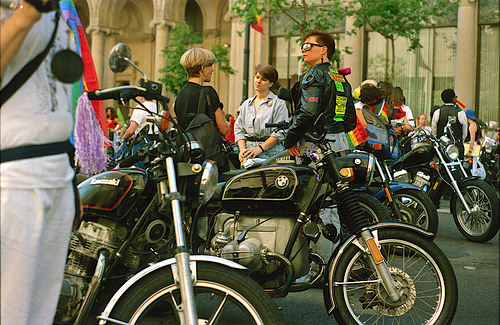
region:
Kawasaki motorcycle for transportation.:
[74, 48, 277, 323]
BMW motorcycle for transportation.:
[228, 127, 450, 323]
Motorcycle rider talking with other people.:
[282, 22, 365, 294]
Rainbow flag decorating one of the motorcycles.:
[328, 107, 398, 169]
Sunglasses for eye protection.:
[297, 35, 332, 55]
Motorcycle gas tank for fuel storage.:
[225, 159, 322, 226]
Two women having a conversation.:
[169, 42, 294, 154]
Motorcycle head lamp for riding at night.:
[180, 150, 236, 214]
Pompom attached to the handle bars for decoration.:
[64, 85, 111, 193]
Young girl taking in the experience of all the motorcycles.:
[411, 107, 438, 165]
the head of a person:
[291, 25, 331, 61]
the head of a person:
[181, 47, 219, 85]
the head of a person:
[248, 56, 282, 94]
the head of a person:
[411, 108, 428, 127]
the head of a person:
[438, 82, 458, 107]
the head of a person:
[462, 105, 480, 127]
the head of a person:
[100, 97, 116, 117]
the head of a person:
[133, 87, 152, 102]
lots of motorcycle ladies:
[1, 0, 498, 322]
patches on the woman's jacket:
[327, 65, 347, 122]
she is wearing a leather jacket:
[278, 62, 355, 146]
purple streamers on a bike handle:
[73, 92, 115, 177]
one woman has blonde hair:
[180, 47, 215, 82]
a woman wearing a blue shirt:
[234, 63, 287, 166]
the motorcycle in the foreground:
[54, 41, 286, 321]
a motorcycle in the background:
[379, 115, 499, 242]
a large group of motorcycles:
[53, 104, 496, 322]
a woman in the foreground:
[2, 0, 74, 324]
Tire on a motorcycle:
[330, 214, 476, 322]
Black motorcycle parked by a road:
[198, 146, 449, 316]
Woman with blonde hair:
[167, 36, 218, 162]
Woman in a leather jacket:
[293, 26, 362, 145]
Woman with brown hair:
[228, 50, 291, 174]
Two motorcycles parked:
[68, 83, 376, 323]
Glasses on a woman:
[291, 31, 343, 73]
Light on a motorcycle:
[434, 134, 474, 179]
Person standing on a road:
[425, 83, 467, 161]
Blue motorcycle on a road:
[325, 106, 433, 233]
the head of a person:
[103, 104, 120, 121]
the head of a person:
[131, 82, 158, 107]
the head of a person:
[383, 79, 406, 106]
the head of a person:
[363, 79, 383, 100]